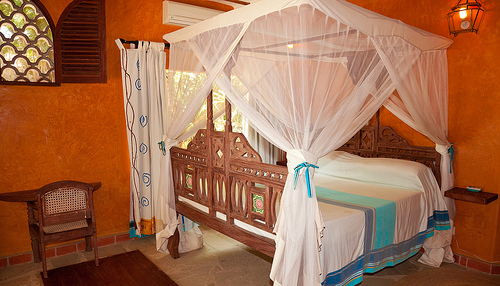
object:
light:
[446, 0, 487, 38]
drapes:
[162, 0, 456, 286]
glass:
[0, 0, 56, 83]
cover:
[56, 0, 108, 83]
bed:
[167, 121, 439, 254]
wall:
[464, 105, 500, 188]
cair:
[0, 180, 104, 264]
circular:
[19, 23, 40, 44]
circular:
[0, 43, 21, 65]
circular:
[21, 67, 43, 83]